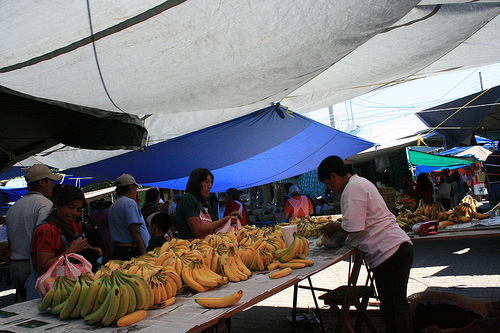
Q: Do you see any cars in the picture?
A: No, there are no cars.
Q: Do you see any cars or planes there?
A: No, there are no cars or planes.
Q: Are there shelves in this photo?
A: No, there are no shelves.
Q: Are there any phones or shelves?
A: No, there are no shelves or phones.